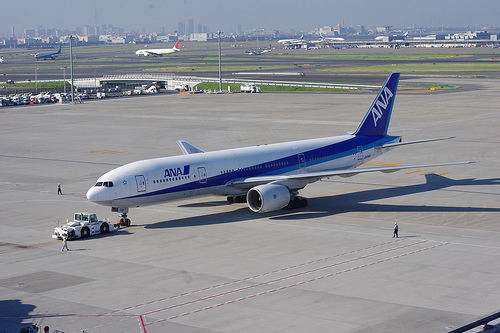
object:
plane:
[86, 72, 476, 228]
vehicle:
[50, 211, 116, 240]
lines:
[100, 235, 410, 318]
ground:
[0, 42, 500, 331]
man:
[58, 233, 69, 252]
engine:
[245, 183, 293, 215]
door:
[134, 173, 147, 193]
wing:
[225, 160, 477, 186]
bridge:
[67, 71, 202, 91]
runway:
[0, 70, 425, 83]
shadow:
[142, 172, 500, 229]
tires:
[125, 218, 131, 227]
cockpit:
[92, 180, 119, 189]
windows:
[153, 179, 156, 184]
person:
[55, 182, 63, 196]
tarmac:
[0, 76, 499, 332]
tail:
[349, 70, 402, 136]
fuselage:
[123, 134, 403, 213]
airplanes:
[134, 39, 182, 59]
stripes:
[259, 137, 385, 177]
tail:
[172, 38, 180, 51]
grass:
[193, 81, 352, 91]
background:
[0, 0, 499, 332]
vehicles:
[239, 83, 262, 93]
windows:
[108, 181, 114, 188]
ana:
[160, 167, 185, 178]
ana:
[370, 84, 394, 127]